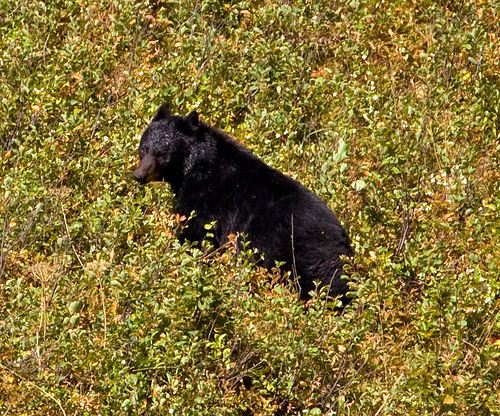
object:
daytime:
[0, 0, 499, 414]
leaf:
[201, 222, 213, 231]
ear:
[187, 108, 200, 124]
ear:
[153, 97, 171, 120]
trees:
[0, 0, 498, 415]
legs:
[172, 197, 208, 243]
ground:
[387, 130, 474, 180]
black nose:
[129, 164, 147, 184]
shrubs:
[0, 0, 500, 408]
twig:
[288, 212, 301, 290]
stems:
[202, 25, 489, 185]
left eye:
[161, 152, 170, 160]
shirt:
[145, 96, 175, 124]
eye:
[139, 147, 146, 156]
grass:
[104, 255, 314, 368]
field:
[1, 0, 500, 413]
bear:
[133, 94, 351, 315]